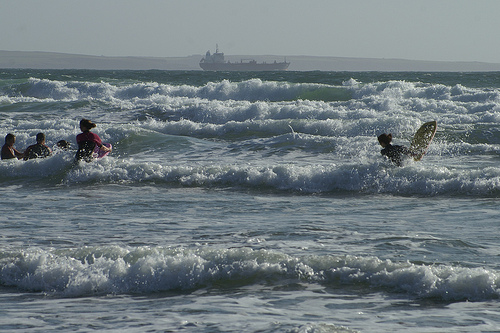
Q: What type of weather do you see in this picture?
A: It is clear.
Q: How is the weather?
A: It is clear.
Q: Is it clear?
A: Yes, it is clear.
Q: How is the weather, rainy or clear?
A: It is clear.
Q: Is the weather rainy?
A: No, it is clear.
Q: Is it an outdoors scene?
A: Yes, it is outdoors.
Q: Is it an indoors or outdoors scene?
A: It is outdoors.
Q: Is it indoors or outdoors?
A: It is outdoors.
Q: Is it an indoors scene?
A: No, it is outdoors.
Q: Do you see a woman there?
A: Yes, there is a woman.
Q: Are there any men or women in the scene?
A: Yes, there is a woman.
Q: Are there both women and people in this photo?
A: Yes, there are both a woman and people.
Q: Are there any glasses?
A: No, there are no glasses.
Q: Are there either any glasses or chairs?
A: No, there are no glasses or chairs.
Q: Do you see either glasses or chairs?
A: No, there are no glasses or chairs.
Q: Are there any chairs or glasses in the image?
A: No, there are no glasses or chairs.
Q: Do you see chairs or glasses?
A: No, there are no glasses or chairs.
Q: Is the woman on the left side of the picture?
A: Yes, the woman is on the left of the image.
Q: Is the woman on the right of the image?
A: No, the woman is on the left of the image.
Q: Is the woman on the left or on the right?
A: The woman is on the left of the image.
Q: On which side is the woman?
A: The woman is on the left of the image.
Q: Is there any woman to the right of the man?
A: Yes, there is a woman to the right of the man.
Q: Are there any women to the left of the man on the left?
A: No, the woman is to the right of the man.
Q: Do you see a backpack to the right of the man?
A: No, there is a woman to the right of the man.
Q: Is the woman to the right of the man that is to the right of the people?
A: Yes, the woman is to the right of the man.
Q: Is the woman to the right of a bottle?
A: No, the woman is to the right of the man.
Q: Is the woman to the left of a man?
A: No, the woman is to the right of a man.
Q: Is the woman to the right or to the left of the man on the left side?
A: The woman is to the right of the man.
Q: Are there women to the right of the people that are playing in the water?
A: Yes, there is a woman to the right of the people.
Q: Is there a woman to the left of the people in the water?
A: No, the woman is to the right of the people.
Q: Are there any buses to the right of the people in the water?
A: No, there is a woman to the right of the people.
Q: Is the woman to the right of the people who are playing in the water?
A: Yes, the woman is to the right of the people.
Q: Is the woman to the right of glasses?
A: No, the woman is to the right of the people.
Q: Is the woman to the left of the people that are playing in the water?
A: No, the woman is to the right of the people.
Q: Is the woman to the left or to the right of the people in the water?
A: The woman is to the right of the people.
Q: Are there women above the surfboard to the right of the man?
A: Yes, there is a woman above the surf board.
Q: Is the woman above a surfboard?
A: Yes, the woman is above a surfboard.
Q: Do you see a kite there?
A: No, there are no kites.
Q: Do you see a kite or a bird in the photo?
A: No, there are no kites or birds.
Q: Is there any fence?
A: No, there are no fences.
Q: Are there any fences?
A: No, there are no fences.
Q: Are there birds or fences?
A: No, there are no fences or birds.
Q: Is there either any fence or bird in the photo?
A: No, there are no fences or birds.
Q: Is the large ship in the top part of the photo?
A: Yes, the ship is in the top of the image.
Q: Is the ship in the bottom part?
A: No, the ship is in the top of the image.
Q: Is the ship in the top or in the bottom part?
A: The ship is in the top of the image.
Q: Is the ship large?
A: Yes, the ship is large.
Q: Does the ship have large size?
A: Yes, the ship is large.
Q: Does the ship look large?
A: Yes, the ship is large.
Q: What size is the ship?
A: The ship is large.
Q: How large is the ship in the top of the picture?
A: The ship is large.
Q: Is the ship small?
A: No, the ship is large.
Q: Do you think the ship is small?
A: No, the ship is large.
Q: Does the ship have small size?
A: No, the ship is large.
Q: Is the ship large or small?
A: The ship is large.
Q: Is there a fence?
A: No, there are no fences.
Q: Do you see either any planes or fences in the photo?
A: No, there are no fences or planes.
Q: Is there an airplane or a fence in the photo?
A: No, there are no fences or airplanes.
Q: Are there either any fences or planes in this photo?
A: No, there are no fences or planes.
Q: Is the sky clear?
A: Yes, the sky is clear.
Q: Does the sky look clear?
A: Yes, the sky is clear.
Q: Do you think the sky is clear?
A: Yes, the sky is clear.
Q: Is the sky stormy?
A: No, the sky is clear.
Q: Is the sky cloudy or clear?
A: The sky is clear.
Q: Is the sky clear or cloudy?
A: The sky is clear.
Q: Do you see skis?
A: No, there are no skis.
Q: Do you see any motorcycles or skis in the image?
A: No, there are no skis or motorcycles.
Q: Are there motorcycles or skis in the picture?
A: No, there are no skis or motorcycles.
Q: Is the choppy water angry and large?
A: No, the water is angry but small.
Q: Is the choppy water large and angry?
A: No, the water is angry but small.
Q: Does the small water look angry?
A: Yes, the water is angry.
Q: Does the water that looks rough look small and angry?
A: Yes, the water is small and angry.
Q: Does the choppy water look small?
A: Yes, the water is small.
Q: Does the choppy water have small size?
A: Yes, the water is small.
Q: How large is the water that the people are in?
A: The water is small.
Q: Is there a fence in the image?
A: No, there are no fences.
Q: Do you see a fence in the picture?
A: No, there are no fences.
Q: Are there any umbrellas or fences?
A: No, there are no fences or umbrellas.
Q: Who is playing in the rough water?
A: The people are playing in the water.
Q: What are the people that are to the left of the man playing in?
A: The people are playing in the water.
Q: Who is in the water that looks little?
A: The people are in the water.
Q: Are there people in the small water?
A: Yes, there are people in the water.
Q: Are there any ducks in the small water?
A: No, there are people in the water.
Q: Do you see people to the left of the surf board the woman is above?
A: Yes, there are people to the left of the surfboard.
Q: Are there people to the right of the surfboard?
A: No, the people are to the left of the surfboard.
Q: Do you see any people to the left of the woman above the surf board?
A: Yes, there are people to the left of the woman.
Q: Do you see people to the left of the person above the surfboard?
A: Yes, there are people to the left of the woman.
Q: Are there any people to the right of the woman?
A: No, the people are to the left of the woman.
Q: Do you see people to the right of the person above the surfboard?
A: No, the people are to the left of the woman.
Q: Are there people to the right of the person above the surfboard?
A: No, the people are to the left of the woman.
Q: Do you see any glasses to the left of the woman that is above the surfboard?
A: No, there are people to the left of the woman.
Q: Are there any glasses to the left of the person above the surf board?
A: No, there are people to the left of the woman.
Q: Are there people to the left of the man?
A: Yes, there are people to the left of the man.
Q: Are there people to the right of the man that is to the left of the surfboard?
A: No, the people are to the left of the man.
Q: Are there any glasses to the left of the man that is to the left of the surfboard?
A: No, there are people to the left of the man.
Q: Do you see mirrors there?
A: No, there are no mirrors.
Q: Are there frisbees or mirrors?
A: No, there are no mirrors or frisbees.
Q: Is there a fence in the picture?
A: No, there are no fences.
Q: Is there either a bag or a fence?
A: No, there are no fences or bags.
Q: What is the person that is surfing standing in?
A: The person is standing in the water.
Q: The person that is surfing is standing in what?
A: The person is standing in the water.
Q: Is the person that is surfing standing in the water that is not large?
A: Yes, the person is standing in the water.